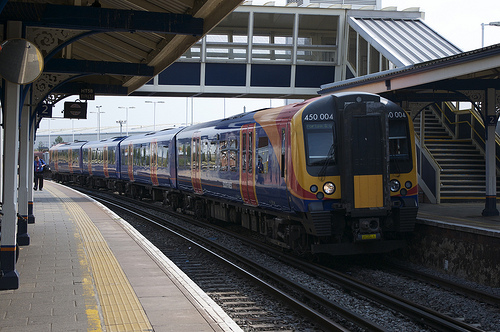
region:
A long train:
[45, 96, 423, 221]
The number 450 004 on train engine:
[288, 87, 424, 258]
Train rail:
[121, 241, 499, 327]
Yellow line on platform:
[43, 182, 160, 329]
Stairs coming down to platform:
[376, 41, 498, 205]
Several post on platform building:
[6, 75, 58, 287]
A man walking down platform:
[29, 151, 52, 193]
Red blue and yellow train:
[48, 101, 388, 227]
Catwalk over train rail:
[151, 6, 440, 96]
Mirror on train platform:
[3, 36, 50, 95]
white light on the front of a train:
[321, 179, 335, 192]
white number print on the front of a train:
[299, 112, 333, 120]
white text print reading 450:
[301, 110, 321, 120]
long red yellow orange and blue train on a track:
[48, 87, 423, 252]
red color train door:
[237, 119, 257, 205]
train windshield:
[307, 133, 337, 173]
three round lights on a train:
[308, 178, 338, 201]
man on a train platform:
[33, 154, 51, 192]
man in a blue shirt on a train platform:
[36, 151, 52, 189]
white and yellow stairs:
[410, 101, 490, 203]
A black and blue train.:
[25, 74, 436, 216]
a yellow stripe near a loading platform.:
[30, 179, 168, 329]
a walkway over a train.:
[128, 0, 473, 93]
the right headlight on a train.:
[311, 176, 347, 198]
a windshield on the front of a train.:
[297, 103, 419, 181]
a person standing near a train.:
[25, 150, 50, 202]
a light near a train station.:
[467, 20, 498, 67]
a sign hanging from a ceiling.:
[48, 93, 96, 122]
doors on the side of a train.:
[229, 116, 264, 194]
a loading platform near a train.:
[0, 178, 247, 329]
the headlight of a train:
[320, 176, 341, 197]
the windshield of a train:
[299, 117, 342, 174]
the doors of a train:
[233, 117, 260, 211]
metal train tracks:
[67, 179, 498, 329]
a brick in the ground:
[28, 292, 83, 317]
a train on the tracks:
[12, 85, 429, 271]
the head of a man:
[33, 151, 43, 165]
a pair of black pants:
[28, 167, 50, 188]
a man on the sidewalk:
[28, 149, 55, 194]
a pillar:
[0, 83, 32, 295]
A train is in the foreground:
[43, 81, 426, 263]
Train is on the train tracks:
[183, 185, 450, 327]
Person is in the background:
[33, 141, 57, 193]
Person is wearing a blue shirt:
[33, 154, 49, 174]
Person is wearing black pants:
[28, 170, 48, 197]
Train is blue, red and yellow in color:
[44, 83, 426, 255]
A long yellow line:
[37, 178, 152, 330]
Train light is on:
[312, 174, 341, 206]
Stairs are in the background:
[403, 103, 490, 203]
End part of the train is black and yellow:
[296, 91, 419, 226]